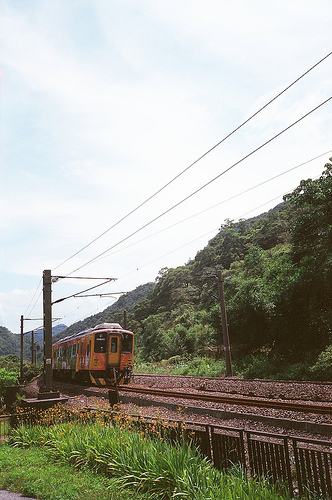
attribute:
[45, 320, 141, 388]
train — yellow, red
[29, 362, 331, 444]
track — rusty, brown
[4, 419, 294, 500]
grass — green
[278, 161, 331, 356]
tree — huge, bushy, green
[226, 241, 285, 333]
tree — huge, bushy, green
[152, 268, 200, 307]
tree — huge, bushy, green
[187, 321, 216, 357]
tree — huge, bushy, green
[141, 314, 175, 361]
tree — green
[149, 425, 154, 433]
flower — yellow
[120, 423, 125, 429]
flower — yellow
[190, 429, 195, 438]
flower — yellow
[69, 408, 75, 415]
flower — yellow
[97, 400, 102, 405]
flower — yellow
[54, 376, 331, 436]
gravel — brown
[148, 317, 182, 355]
tree — huge, bushy, green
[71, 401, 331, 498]
gate — iron, brown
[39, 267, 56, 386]
telephone post — brown, electric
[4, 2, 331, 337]
sky — cloudy, blue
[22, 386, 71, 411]
base — cement